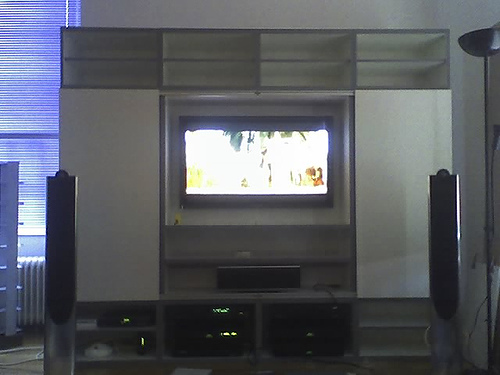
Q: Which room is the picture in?
A: It is at the living room.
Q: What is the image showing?
A: It is showing a living room.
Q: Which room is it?
A: It is a living room.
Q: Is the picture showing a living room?
A: Yes, it is showing a living room.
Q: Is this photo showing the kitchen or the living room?
A: It is showing the living room.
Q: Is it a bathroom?
A: No, it is a living room.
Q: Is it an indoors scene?
A: Yes, it is indoors.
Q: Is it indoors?
A: Yes, it is indoors.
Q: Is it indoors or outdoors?
A: It is indoors.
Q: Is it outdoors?
A: No, it is indoors.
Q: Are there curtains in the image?
A: No, there are no curtains.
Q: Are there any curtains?
A: No, there are no curtains.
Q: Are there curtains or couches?
A: No, there are no curtains or couches.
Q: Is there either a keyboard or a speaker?
A: Yes, there is a speaker.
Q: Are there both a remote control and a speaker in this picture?
A: No, there is a speaker but no remote controls.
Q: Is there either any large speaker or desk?
A: Yes, there is a large speaker.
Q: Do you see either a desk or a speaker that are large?
A: Yes, the speaker is large.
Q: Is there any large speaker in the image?
A: Yes, there is a large speaker.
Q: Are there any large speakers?
A: Yes, there is a large speaker.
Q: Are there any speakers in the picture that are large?
A: Yes, there is a speaker that is large.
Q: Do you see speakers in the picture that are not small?
A: Yes, there is a large speaker.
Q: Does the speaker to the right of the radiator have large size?
A: Yes, the speaker is large.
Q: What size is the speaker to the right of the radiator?
A: The speaker is large.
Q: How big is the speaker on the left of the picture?
A: The speaker is large.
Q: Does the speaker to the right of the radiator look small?
A: No, the speaker is large.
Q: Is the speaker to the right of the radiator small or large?
A: The speaker is large.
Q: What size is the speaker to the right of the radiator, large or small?
A: The speaker is large.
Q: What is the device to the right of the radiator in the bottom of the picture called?
A: The device is a speaker.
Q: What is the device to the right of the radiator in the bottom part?
A: The device is a speaker.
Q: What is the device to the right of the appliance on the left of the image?
A: The device is a speaker.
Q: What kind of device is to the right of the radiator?
A: The device is a speaker.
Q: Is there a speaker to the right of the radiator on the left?
A: Yes, there is a speaker to the right of the radiator.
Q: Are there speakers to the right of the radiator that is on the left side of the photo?
A: Yes, there is a speaker to the right of the radiator.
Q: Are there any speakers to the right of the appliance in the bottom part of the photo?
A: Yes, there is a speaker to the right of the radiator.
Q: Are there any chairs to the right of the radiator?
A: No, there is a speaker to the right of the radiator.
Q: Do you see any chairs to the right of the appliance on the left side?
A: No, there is a speaker to the right of the radiator.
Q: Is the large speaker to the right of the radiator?
A: Yes, the speaker is to the right of the radiator.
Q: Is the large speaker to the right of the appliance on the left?
A: Yes, the speaker is to the right of the radiator.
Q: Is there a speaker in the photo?
A: Yes, there is a speaker.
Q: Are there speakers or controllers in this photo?
A: Yes, there is a speaker.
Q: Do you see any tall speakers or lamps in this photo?
A: Yes, there is a tall speaker.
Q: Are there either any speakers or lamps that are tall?
A: Yes, the speaker is tall.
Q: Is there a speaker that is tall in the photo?
A: Yes, there is a tall speaker.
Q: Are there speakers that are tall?
A: Yes, there is a speaker that is tall.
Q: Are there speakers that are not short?
A: Yes, there is a tall speaker.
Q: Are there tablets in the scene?
A: No, there are no tablets.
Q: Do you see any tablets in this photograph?
A: No, there are no tablets.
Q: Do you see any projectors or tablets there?
A: No, there are no tablets or projectors.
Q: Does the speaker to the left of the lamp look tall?
A: Yes, the speaker is tall.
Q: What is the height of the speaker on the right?
A: The speaker is tall.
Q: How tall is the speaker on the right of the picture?
A: The speaker is tall.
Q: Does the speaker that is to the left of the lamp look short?
A: No, the speaker is tall.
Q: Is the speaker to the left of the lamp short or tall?
A: The speaker is tall.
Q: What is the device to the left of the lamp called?
A: The device is a speaker.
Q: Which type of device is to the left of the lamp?
A: The device is a speaker.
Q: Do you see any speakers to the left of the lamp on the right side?
A: Yes, there is a speaker to the left of the lamp.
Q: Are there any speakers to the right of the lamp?
A: No, the speaker is to the left of the lamp.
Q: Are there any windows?
A: Yes, there is a window.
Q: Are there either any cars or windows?
A: Yes, there is a window.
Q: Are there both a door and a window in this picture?
A: No, there is a window but no doors.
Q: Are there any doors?
A: No, there are no doors.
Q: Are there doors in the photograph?
A: No, there are no doors.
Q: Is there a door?
A: No, there are no doors.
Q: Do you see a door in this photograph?
A: No, there are no doors.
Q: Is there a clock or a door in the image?
A: No, there are no doors or clocks.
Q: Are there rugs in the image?
A: No, there are no rugs.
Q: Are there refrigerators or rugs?
A: No, there are no rugs or refrigerators.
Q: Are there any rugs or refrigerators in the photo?
A: No, there are no rugs or refrigerators.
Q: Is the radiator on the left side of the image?
A: Yes, the radiator is on the left of the image.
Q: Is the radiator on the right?
A: No, the radiator is on the left of the image.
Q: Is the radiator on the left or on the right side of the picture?
A: The radiator is on the left of the image.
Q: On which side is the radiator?
A: The radiator is on the left of the image.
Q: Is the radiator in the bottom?
A: Yes, the radiator is in the bottom of the image.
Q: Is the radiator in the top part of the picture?
A: No, the radiator is in the bottom of the image.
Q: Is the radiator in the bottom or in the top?
A: The radiator is in the bottom of the image.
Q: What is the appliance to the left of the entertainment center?
A: The appliance is a radiator.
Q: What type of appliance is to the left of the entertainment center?
A: The appliance is a radiator.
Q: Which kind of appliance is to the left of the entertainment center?
A: The appliance is a radiator.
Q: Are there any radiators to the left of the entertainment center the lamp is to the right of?
A: Yes, there is a radiator to the left of the entertainment center.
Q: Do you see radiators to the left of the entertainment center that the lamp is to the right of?
A: Yes, there is a radiator to the left of the entertainment center.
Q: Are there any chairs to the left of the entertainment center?
A: No, there is a radiator to the left of the entertainment center.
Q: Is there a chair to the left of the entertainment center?
A: No, there is a radiator to the left of the entertainment center.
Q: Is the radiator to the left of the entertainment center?
A: Yes, the radiator is to the left of the entertainment center.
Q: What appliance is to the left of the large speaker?
A: The appliance is a radiator.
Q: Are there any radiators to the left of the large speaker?
A: Yes, there is a radiator to the left of the speaker.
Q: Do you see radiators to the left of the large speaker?
A: Yes, there is a radiator to the left of the speaker.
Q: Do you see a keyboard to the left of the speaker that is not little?
A: No, there is a radiator to the left of the speaker.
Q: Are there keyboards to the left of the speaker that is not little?
A: No, there is a radiator to the left of the speaker.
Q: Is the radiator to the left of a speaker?
A: Yes, the radiator is to the left of a speaker.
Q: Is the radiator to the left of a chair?
A: No, the radiator is to the left of a speaker.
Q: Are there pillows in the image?
A: No, there are no pillows.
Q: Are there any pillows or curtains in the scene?
A: No, there are no pillows or curtains.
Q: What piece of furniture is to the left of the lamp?
A: The piece of furniture is an entertainment center.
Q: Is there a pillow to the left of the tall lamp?
A: No, there is an entertainment center to the left of the lamp.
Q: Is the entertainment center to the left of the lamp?
A: Yes, the entertainment center is to the left of the lamp.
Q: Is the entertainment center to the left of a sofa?
A: No, the entertainment center is to the left of the lamp.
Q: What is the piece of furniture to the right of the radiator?
A: The piece of furniture is an entertainment center.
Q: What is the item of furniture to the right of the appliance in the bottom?
A: The piece of furniture is an entertainment center.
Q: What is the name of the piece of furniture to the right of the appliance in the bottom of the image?
A: The piece of furniture is an entertainment center.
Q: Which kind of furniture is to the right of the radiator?
A: The piece of furniture is an entertainment center.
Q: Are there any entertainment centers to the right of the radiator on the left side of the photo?
A: Yes, there is an entertainment center to the right of the radiator.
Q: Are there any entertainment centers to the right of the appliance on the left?
A: Yes, there is an entertainment center to the right of the radiator.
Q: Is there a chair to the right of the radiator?
A: No, there is an entertainment center to the right of the radiator.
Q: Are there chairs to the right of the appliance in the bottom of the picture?
A: No, there is an entertainment center to the right of the radiator.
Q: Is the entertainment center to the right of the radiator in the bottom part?
A: Yes, the entertainment center is to the right of the radiator.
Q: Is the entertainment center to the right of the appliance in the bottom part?
A: Yes, the entertainment center is to the right of the radiator.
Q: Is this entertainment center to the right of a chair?
A: No, the entertainment center is to the right of the radiator.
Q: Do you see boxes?
A: No, there are no boxes.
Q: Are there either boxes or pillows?
A: No, there are no boxes or pillows.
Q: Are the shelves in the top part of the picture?
A: Yes, the shelves are in the top of the image.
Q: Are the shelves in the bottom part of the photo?
A: No, the shelves are in the top of the image.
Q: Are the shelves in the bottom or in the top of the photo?
A: The shelves are in the top of the image.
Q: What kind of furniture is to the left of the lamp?
A: The pieces of furniture are shelves.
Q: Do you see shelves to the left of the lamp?
A: Yes, there are shelves to the left of the lamp.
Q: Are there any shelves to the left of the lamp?
A: Yes, there are shelves to the left of the lamp.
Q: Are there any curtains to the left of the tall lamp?
A: No, there are shelves to the left of the lamp.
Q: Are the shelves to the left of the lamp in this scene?
A: Yes, the shelves are to the left of the lamp.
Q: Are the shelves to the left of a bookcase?
A: No, the shelves are to the left of the lamp.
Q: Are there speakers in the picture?
A: Yes, there is a speaker.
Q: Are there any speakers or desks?
A: Yes, there is a speaker.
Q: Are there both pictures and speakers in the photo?
A: No, there is a speaker but no pictures.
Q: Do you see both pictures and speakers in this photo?
A: No, there is a speaker but no pictures.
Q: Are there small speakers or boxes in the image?
A: Yes, there is a small speaker.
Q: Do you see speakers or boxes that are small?
A: Yes, the speaker is small.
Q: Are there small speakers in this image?
A: Yes, there is a small speaker.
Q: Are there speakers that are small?
A: Yes, there is a speaker that is small.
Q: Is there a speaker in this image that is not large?
A: Yes, there is a small speaker.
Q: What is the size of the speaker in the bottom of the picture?
A: The speaker is small.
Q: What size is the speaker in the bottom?
A: The speaker is small.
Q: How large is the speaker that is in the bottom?
A: The speaker is small.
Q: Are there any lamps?
A: Yes, there is a lamp.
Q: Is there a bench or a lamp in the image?
A: Yes, there is a lamp.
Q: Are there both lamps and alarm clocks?
A: No, there is a lamp but no alarm clocks.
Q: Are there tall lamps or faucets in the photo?
A: Yes, there is a tall lamp.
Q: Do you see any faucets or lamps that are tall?
A: Yes, the lamp is tall.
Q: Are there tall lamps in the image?
A: Yes, there is a tall lamp.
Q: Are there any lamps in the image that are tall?
A: Yes, there is a lamp that is tall.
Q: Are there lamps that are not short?
A: Yes, there is a tall lamp.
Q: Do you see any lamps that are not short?
A: Yes, there is a tall lamp.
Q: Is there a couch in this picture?
A: No, there are no couches.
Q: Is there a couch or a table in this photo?
A: No, there are no couches or tables.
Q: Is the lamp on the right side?
A: Yes, the lamp is on the right of the image.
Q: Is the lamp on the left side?
A: No, the lamp is on the right of the image.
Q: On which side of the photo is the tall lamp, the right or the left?
A: The lamp is on the right of the image.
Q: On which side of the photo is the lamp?
A: The lamp is on the right of the image.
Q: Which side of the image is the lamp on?
A: The lamp is on the right of the image.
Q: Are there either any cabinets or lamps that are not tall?
A: No, there is a lamp but it is tall.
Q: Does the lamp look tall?
A: Yes, the lamp is tall.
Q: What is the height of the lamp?
A: The lamp is tall.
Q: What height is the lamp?
A: The lamp is tall.